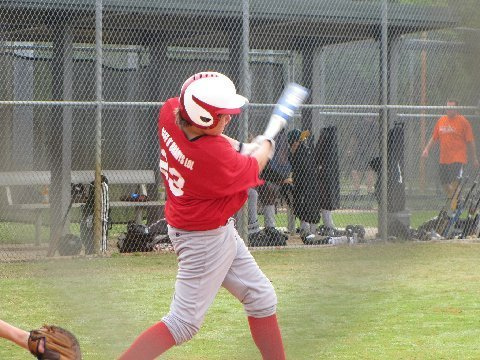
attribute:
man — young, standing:
[84, 53, 323, 356]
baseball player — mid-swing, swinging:
[93, 52, 328, 359]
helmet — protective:
[149, 48, 251, 139]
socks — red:
[245, 311, 300, 359]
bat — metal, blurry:
[253, 70, 318, 145]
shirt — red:
[419, 105, 476, 168]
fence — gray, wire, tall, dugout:
[27, 28, 117, 116]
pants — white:
[138, 214, 290, 340]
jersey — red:
[139, 101, 265, 223]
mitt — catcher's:
[29, 319, 76, 359]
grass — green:
[283, 252, 479, 359]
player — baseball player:
[171, 51, 240, 116]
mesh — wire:
[35, 31, 80, 70]